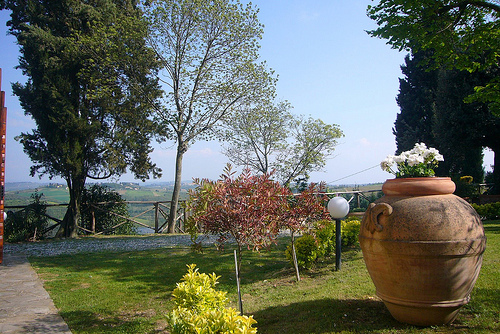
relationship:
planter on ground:
[359, 179, 486, 326] [1, 211, 499, 333]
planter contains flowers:
[359, 179, 486, 326] [380, 142, 444, 179]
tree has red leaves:
[179, 162, 330, 309] [187, 164, 329, 249]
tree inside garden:
[179, 162, 330, 309] [1, 211, 499, 333]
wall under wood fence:
[2, 220, 366, 261] [5, 190, 393, 243]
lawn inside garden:
[30, 226, 498, 333] [2, 189, 499, 333]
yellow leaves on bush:
[166, 264, 258, 332] [165, 264, 258, 333]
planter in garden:
[359, 179, 486, 326] [2, 189, 499, 333]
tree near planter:
[179, 162, 330, 309] [359, 179, 486, 326]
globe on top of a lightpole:
[327, 196, 350, 217] [334, 220, 341, 270]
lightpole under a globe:
[334, 220, 341, 270] [327, 196, 350, 217]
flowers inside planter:
[380, 142, 444, 179] [359, 179, 486, 326]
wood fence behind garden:
[5, 190, 393, 243] [2, 189, 499, 333]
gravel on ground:
[3, 217, 361, 258] [1, 211, 499, 333]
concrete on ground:
[1, 256, 73, 332] [1, 211, 499, 333]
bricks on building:
[2, 89, 7, 265] [1, 81, 6, 266]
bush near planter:
[286, 219, 361, 273] [359, 179, 486, 326]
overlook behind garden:
[4, 18, 498, 238] [2, 189, 499, 333]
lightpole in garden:
[327, 196, 349, 271] [2, 189, 499, 333]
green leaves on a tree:
[366, 1, 499, 120] [179, 162, 330, 309]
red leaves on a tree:
[187, 164, 329, 249] [179, 162, 330, 309]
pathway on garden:
[1, 256, 73, 332] [2, 189, 499, 333]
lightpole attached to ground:
[327, 196, 349, 271] [1, 211, 499, 333]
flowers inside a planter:
[380, 142, 444, 179] [359, 179, 486, 326]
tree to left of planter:
[179, 162, 330, 309] [359, 179, 486, 326]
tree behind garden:
[2, 1, 171, 240] [2, 189, 499, 333]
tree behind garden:
[393, 3, 496, 203] [2, 189, 499, 333]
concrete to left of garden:
[1, 256, 73, 332] [2, 189, 499, 333]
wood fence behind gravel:
[5, 190, 393, 243] [3, 217, 361, 258]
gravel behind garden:
[3, 217, 361, 258] [2, 189, 499, 333]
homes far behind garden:
[48, 182, 141, 190] [2, 189, 499, 333]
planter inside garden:
[359, 179, 486, 326] [2, 189, 499, 333]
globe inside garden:
[327, 196, 350, 217] [2, 189, 499, 333]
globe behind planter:
[327, 196, 350, 217] [359, 179, 486, 326]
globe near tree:
[327, 196, 350, 217] [179, 162, 330, 309]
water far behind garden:
[131, 223, 162, 235] [2, 189, 499, 333]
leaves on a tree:
[366, 1, 499, 120] [393, 3, 496, 203]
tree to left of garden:
[2, 1, 171, 240] [2, 189, 499, 333]